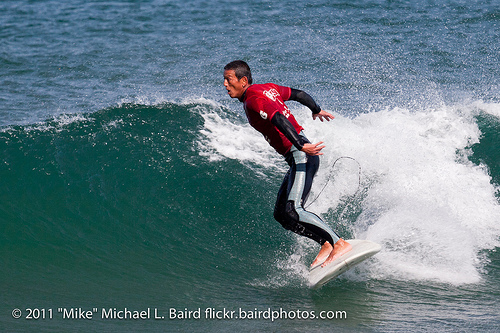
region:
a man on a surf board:
[195, 52, 397, 304]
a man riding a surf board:
[213, 47, 371, 307]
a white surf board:
[300, 219, 377, 303]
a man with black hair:
[209, 35, 264, 107]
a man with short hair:
[207, 49, 254, 114]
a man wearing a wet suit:
[243, 56, 333, 270]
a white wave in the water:
[395, 84, 482, 301]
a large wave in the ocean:
[53, 114, 235, 242]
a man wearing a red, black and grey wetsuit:
[232, 39, 319, 276]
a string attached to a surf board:
[295, 142, 367, 244]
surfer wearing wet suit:
[191, 52, 369, 276]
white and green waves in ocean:
[47, 42, 84, 96]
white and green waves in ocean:
[168, 199, 223, 257]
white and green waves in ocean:
[390, 135, 437, 220]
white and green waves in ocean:
[44, 138, 105, 196]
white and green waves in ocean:
[84, 36, 122, 80]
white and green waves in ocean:
[40, 208, 120, 265]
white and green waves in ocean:
[350, 33, 405, 118]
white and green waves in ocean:
[95, 56, 165, 137]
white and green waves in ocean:
[45, 42, 100, 116]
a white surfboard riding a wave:
[315, 236, 385, 290]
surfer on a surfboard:
[220, 58, 382, 289]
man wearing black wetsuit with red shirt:
[223, 58, 350, 265]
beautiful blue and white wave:
[9, 103, 489, 293]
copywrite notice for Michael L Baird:
[11, 307, 199, 320]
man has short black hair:
[223, 58, 254, 84]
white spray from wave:
[280, 36, 446, 106]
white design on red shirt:
[258, 106, 271, 122]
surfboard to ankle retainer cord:
[306, 155, 364, 229]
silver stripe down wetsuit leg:
[286, 148, 336, 254]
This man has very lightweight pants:
[291, 131, 356, 278]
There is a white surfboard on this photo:
[314, 238, 356, 309]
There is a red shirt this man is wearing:
[253, 100, 285, 149]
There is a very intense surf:
[391, 153, 411, 228]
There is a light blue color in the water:
[171, 155, 198, 232]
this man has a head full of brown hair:
[228, 55, 254, 87]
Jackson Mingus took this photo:
[188, 23, 360, 286]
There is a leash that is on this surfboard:
[317, 172, 355, 223]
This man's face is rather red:
[228, 74, 240, 104]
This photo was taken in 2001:
[27, 307, 45, 332]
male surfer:
[207, 51, 345, 258]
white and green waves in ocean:
[35, 22, 137, 92]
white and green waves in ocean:
[117, 95, 148, 120]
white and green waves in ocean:
[60, 158, 97, 200]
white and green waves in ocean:
[131, 173, 193, 228]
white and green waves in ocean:
[8, 169, 119, 260]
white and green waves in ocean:
[354, 42, 454, 99]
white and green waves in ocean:
[412, 145, 476, 199]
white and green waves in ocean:
[74, 46, 126, 104]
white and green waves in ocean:
[75, 139, 153, 221]